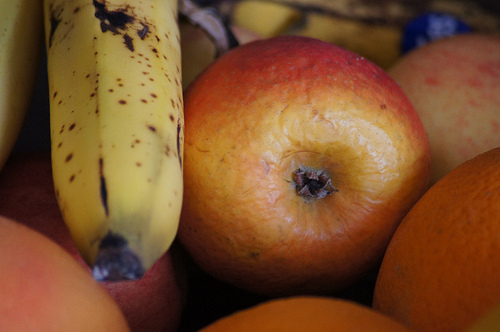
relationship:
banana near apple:
[34, 1, 191, 284] [173, 27, 436, 298]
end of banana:
[91, 229, 159, 287] [34, 1, 191, 284]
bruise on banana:
[92, 6, 145, 46] [34, 1, 191, 284]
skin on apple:
[261, 75, 355, 122] [173, 27, 436, 298]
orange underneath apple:
[245, 297, 357, 318] [173, 27, 436, 298]